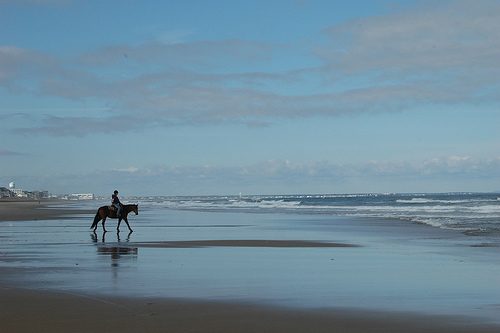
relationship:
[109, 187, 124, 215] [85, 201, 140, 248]
man sitting in horse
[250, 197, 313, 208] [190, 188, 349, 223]
waves in sea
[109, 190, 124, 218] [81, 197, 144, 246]
man on horse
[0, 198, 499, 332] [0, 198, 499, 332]
sand on sand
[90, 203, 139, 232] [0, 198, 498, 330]
horse on sand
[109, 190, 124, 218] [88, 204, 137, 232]
man on horse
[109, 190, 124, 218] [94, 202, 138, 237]
man on horse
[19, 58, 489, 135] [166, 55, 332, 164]
grey clouds in sky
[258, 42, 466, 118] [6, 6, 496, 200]
clouds in sky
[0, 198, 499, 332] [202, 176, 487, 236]
sand by ocean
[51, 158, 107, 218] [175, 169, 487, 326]
building by ocean